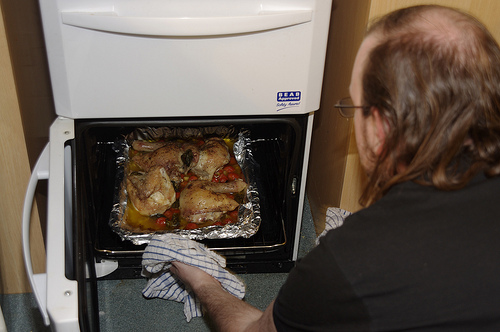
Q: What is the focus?
A: Man cooking.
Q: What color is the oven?
A: White.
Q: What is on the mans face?
A: Eye glasses.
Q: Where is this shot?
A: Kitchen.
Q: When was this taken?
A: Daytime.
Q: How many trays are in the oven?
A: 1.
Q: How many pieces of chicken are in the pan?
A: 4.